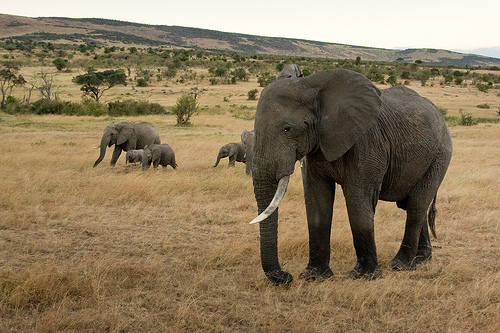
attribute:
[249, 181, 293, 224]
left tusk — white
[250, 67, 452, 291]
elephant — standing alone, gray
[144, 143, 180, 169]
elephant — juvenile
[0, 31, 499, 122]
trees — green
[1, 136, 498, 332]
grass — brown, dry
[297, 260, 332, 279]
foot — gray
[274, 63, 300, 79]
right ear — large